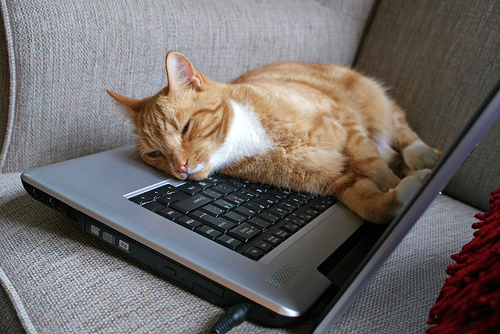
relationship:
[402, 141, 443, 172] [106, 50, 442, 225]
paw of cat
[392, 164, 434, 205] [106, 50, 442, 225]
paw of cat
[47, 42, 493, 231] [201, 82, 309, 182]
cat has ruff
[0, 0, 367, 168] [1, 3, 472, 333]
pillow on chair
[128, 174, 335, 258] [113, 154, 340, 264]
black keys are on keyboard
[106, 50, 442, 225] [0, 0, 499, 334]
cat on chair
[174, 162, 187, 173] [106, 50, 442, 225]
nose on cat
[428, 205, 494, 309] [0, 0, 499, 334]
pillow on chair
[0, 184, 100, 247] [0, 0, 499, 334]
shadow on chair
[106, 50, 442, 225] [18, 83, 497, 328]
cat on laptop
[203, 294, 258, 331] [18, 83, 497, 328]
cord in laptop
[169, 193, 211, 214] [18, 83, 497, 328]
black keys are on laptop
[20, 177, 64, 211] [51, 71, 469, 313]
holes are in laptop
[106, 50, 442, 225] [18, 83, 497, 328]
cat laying on laptop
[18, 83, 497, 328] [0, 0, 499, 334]
laptop on chair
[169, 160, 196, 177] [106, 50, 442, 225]
nose on cat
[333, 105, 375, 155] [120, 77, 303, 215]
stripes are on cat